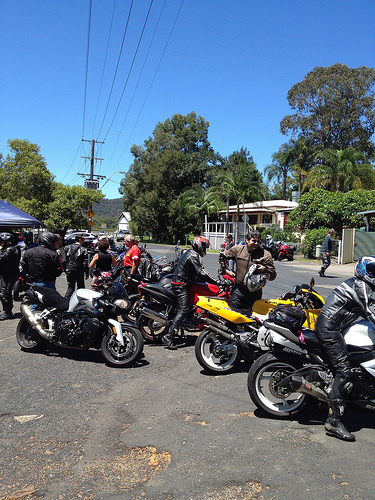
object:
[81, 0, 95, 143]
cables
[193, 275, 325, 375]
motorcycle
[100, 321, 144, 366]
wheel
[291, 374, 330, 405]
pipe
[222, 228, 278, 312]
bikers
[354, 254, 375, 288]
helmet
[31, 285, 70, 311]
seat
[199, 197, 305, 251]
house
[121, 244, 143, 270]
shirt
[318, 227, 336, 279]
man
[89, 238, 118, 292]
woman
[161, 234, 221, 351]
rider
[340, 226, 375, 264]
fencing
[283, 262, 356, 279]
sidewalk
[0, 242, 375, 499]
street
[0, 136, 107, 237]
trees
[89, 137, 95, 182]
pole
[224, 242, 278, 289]
jacket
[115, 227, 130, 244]
car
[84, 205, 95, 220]
sign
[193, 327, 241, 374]
tire